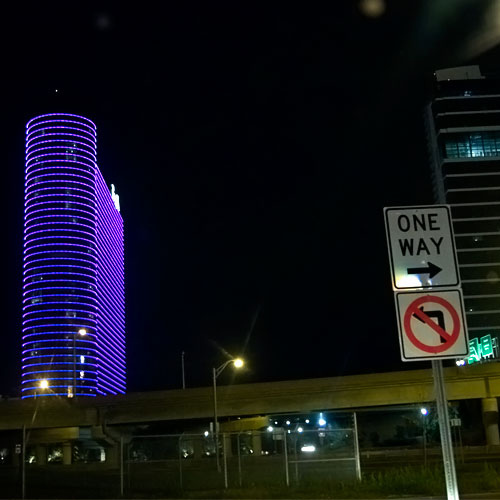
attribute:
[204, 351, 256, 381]
light — yellow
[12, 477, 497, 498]
street — light